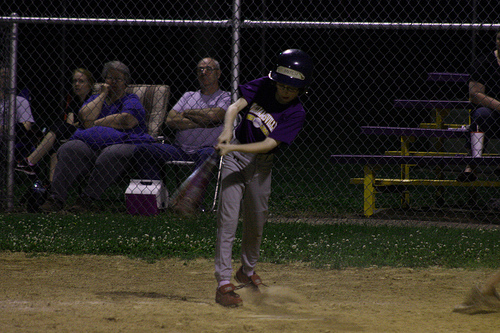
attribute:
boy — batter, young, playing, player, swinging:
[238, 78, 286, 151]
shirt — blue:
[228, 96, 274, 119]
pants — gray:
[226, 220, 261, 259]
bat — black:
[199, 151, 223, 206]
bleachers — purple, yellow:
[360, 116, 426, 161]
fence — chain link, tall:
[328, 22, 374, 62]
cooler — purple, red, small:
[136, 176, 155, 213]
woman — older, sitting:
[85, 68, 151, 142]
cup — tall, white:
[464, 134, 484, 156]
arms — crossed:
[166, 102, 214, 129]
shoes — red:
[208, 256, 256, 308]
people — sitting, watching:
[103, 93, 199, 166]